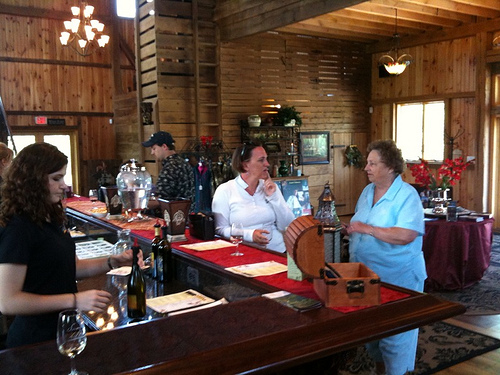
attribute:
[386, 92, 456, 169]
window — bright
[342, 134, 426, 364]
lady — standing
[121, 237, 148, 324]
bottle — alcohol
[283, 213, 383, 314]
box — open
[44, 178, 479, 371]
counter — wooden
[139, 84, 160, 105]
board — brown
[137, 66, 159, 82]
board — brown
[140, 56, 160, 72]
board — brown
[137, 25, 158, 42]
board — brown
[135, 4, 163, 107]
board — brown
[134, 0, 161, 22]
board — brown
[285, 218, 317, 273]
board — brown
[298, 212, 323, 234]
board — brown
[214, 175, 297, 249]
shirt — white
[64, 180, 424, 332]
runner — red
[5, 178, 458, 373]
top — counter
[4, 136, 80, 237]
hair — woman's, brown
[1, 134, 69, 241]
hair — wavy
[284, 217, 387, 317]
box — wooden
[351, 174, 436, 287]
shirt — light blue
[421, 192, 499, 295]
table — round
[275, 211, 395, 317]
chest — small, wooden, treasure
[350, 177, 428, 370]
outfit — light blue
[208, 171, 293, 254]
shirt — white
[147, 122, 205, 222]
man — black, baseball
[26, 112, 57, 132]
sign — exit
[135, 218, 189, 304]
bottles — alcohol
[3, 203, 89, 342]
shirt — black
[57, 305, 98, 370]
glass — wine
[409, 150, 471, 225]
vase — silver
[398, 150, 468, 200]
flowers — red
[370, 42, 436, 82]
fixture — lovely, light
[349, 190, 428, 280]
shirt — blue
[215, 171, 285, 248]
shirt — white